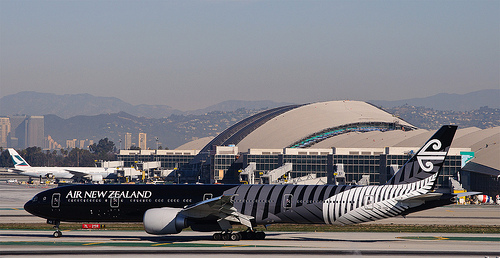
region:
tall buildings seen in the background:
[0, 114, 46, 147]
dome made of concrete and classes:
[194, 98, 409, 149]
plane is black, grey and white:
[20, 123, 458, 235]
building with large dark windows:
[124, 145, 406, 181]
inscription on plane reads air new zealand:
[60, 188, 152, 200]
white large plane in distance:
[7, 145, 147, 179]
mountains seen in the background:
[46, 90, 209, 140]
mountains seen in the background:
[395, 82, 496, 123]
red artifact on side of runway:
[80, 223, 103, 229]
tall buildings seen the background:
[117, 129, 147, 151]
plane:
[40, 162, 441, 233]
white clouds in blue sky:
[332, 21, 384, 52]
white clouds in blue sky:
[391, 41, 431, 69]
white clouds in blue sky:
[162, 42, 230, 93]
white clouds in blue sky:
[244, 36, 272, 70]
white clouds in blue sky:
[171, 36, 193, 54]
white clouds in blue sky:
[108, 45, 152, 80]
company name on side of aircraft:
[62, 189, 157, 201]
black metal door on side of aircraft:
[47, 190, 64, 211]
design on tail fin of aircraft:
[418, 137, 450, 172]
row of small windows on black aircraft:
[61, 195, 109, 205]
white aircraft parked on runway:
[4, 144, 131, 183]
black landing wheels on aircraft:
[44, 228, 66, 239]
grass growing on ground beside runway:
[387, 221, 497, 235]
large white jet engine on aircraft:
[139, 207, 186, 235]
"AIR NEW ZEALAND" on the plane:
[66, 187, 153, 201]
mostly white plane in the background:
[5, 149, 119, 181]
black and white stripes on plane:
[220, 181, 433, 222]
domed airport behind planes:
[170, 100, 499, 152]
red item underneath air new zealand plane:
[71, 221, 106, 233]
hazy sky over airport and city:
[2, 4, 499, 92]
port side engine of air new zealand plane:
[135, 203, 187, 237]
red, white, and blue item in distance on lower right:
[475, 187, 495, 209]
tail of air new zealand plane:
[384, 122, 465, 182]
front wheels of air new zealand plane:
[40, 222, 68, 239]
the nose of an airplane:
[16, 180, 65, 240]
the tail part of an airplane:
[383, 96, 483, 226]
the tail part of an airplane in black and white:
[359, 93, 471, 239]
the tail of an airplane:
[357, 103, 472, 223]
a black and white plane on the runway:
[25, 122, 475, 244]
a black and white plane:
[11, 120, 461, 242]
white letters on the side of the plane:
[21, 174, 162, 232]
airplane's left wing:
[129, 185, 260, 237]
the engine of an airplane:
[139, 190, 249, 242]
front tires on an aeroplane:
[35, 212, 72, 244]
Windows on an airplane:
[324, 196, 346, 208]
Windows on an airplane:
[296, 197, 325, 208]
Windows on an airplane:
[320, 196, 351, 211]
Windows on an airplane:
[146, 193, 180, 208]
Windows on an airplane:
[132, 198, 173, 205]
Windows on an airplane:
[74, 194, 100, 209]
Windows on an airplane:
[141, 195, 174, 210]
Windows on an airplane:
[253, 198, 281, 208]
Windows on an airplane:
[308, 196, 354, 208]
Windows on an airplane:
[251, 195, 271, 207]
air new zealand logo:
[61, 183, 165, 200]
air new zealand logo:
[58, 171, 158, 205]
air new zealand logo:
[58, 175, 163, 213]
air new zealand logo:
[59, 168, 161, 210]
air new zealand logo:
[58, 177, 158, 202]